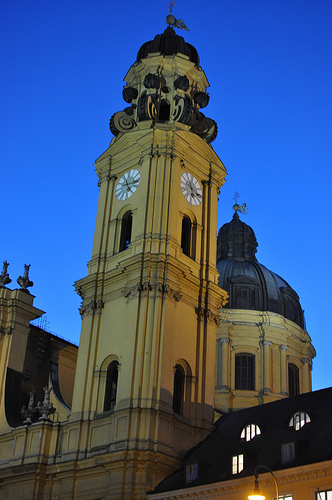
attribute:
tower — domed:
[211, 193, 316, 402]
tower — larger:
[64, 1, 231, 425]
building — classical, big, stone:
[1, 1, 329, 497]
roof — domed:
[216, 212, 306, 329]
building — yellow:
[82, 172, 224, 469]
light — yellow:
[246, 466, 281, 499]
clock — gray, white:
[114, 166, 141, 200]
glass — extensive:
[217, 194, 304, 336]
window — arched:
[89, 350, 123, 414]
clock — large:
[173, 169, 204, 209]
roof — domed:
[108, 27, 219, 141]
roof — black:
[137, 27, 200, 73]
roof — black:
[149, 386, 331, 496]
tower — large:
[69, 4, 229, 497]